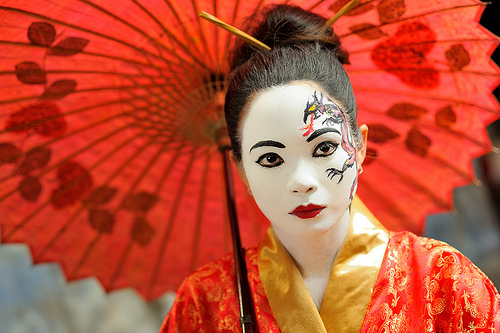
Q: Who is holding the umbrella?
A: A woman.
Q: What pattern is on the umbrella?
A: Flowers and leaves.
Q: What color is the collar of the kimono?
A: Gold.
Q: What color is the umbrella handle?
A: Black.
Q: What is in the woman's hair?
A: Chopsticks.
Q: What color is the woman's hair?
A: Black.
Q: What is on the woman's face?
A: Paint.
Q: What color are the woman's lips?
A: Red.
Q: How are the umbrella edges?
A: Pointed.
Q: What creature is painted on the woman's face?
A: A dragon.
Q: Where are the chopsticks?
A: Hair.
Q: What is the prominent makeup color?
A: White.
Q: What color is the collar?
A: Gold.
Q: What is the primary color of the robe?
A: Red.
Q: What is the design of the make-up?
A: Dragon.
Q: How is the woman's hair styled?
A: In a bun.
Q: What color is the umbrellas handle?
A: Black.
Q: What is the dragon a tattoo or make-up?
A: Makeup.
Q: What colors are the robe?
A: Red and gold.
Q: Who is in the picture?
A: A woman.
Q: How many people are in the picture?
A: 1.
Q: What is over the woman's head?
A: A umbrella.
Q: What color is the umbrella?
A: Red.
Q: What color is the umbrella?
A: Red.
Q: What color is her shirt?
A: Red and gold.